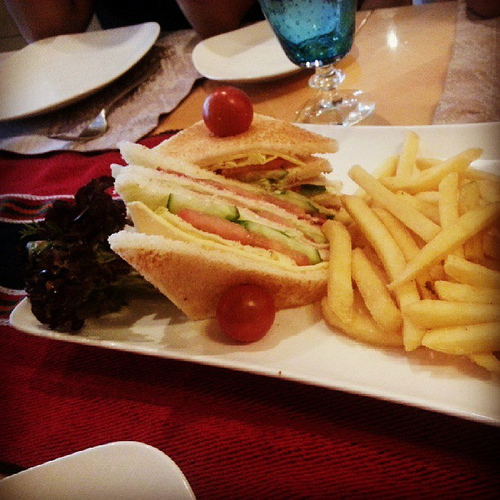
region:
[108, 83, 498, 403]
A sandwich and french fries on a plate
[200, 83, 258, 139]
A small round cherry tomato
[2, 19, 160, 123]
an oddly shaped white plate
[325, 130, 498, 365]
A pile of french fries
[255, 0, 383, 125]
A blue drinking glass with a clear stem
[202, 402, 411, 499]
Random pattern on a red and black tablecloth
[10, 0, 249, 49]
A person's elbows on a dinner table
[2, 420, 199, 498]
The corner of a white plate sitting on a dinner table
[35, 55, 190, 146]
A metal dinner fork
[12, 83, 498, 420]
Food sitting on a plate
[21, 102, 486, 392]
white tray with sandwich and french fries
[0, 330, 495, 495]
red fabric with black marks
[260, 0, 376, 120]
blue stemmed glass with dots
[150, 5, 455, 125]
shine on blonde wooden table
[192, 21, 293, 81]
small empty white plate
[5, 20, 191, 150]
covered plate with fork on mat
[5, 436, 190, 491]
curve of corner of plate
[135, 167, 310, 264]
lettuce, cucumber and cheese filling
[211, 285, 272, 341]
red cherry tomato as garnish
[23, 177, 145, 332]
black tarantula with beady eyes on corner of plate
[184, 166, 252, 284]
There is a sandwich that is very tasty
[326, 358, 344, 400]
There is a white plate that is lovely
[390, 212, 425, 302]
There are french fries that are delivered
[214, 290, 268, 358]
There is a tomato that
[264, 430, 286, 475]
There is a dark red tablecloth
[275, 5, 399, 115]
There is a glass that is blue and white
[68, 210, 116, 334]
There are purple and green lettuce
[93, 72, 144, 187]
There are silver forks that are visible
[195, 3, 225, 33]
This person has her elbows on the table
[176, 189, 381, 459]
Jackson Mingus took the photo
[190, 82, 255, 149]
a cherry tomato on top of a sandwich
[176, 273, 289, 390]
a cherry tomato on a plate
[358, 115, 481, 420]
french fries on a plate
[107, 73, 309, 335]
a sandwich cut in two halves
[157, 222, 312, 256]
sliced tomato on a sandwich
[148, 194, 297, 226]
sliced cucumbers on a sandwich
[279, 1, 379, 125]
a blue drinking glass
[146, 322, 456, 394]
a white plate on a table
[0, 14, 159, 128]
a empty plate on a table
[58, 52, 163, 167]
a silver fork on a table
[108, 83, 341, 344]
Club sandwich on a plate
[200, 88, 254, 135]
Cherry tomato on top of sandwich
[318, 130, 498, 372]
French fries next to sandwich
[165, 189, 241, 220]
Slice of cucumber on sandwich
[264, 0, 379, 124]
Blue glass behind tray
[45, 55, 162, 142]
Fork next to empty plate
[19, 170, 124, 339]
Brocolli next to sandwich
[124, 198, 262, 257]
Slice of cheese on sandwich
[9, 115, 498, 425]
White rectangular plate under food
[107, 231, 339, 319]
Toasted bread